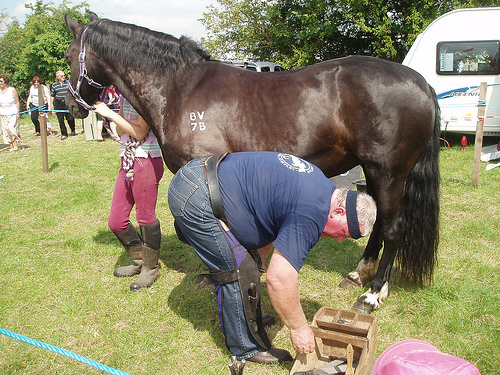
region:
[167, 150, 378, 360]
man bending over box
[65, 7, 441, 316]
tall brown horse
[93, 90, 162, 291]
girl wearing pink pants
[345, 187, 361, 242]
blue sweat band around head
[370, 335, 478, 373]
pink bag on grass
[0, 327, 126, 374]
blue rope across grass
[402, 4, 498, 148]
white travel trailer parked on grass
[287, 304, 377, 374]
wooden tool box on ground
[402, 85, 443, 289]
long black horse tail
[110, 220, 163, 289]
brown riding boots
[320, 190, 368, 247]
man with sunburned face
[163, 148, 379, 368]
man hunched forward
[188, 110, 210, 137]
white letters on brown horse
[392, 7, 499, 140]
white and blue trailer behind grass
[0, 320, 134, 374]
green hose on grass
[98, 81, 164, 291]
woman standing by horse's neck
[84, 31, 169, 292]
horse blocks woman's face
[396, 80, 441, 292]
horse with black tail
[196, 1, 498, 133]
lush green tree behind white tent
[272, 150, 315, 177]
white logo on blue t-shirt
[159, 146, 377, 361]
a man bent over in a blue shirt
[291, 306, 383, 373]
a wooden box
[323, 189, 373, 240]
a man in a black bandanna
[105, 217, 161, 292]
a pair of brown boots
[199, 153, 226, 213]
a black leather belt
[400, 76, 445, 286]
a bushy black horse tail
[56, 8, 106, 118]
a black horse with a pink rein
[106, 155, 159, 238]
a pair of pink pants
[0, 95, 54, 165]
a wooden post with blue string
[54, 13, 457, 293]
a black horse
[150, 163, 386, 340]
person that is bent over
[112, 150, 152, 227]
person wearing red pants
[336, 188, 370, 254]
man wearing a head band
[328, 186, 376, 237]
man with grey head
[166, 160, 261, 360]
man wearing blue jeans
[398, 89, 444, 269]
horse with long black hair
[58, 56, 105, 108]
horse with strap on its face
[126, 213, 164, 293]
person wearing brown boots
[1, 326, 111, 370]
blue rope on the ground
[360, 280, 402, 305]
horse with white feet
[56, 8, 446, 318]
muscular dark brown horse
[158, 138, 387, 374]
older man with a red face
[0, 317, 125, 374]
twisted blue green rope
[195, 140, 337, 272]
wrinkled navy blue tee shirt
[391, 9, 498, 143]
parked white camper with a window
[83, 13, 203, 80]
wavy black horse's mane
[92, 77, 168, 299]
girl wearing tight red pants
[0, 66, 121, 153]
group of people observing horses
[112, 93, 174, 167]
pink, green, and white striped shirt